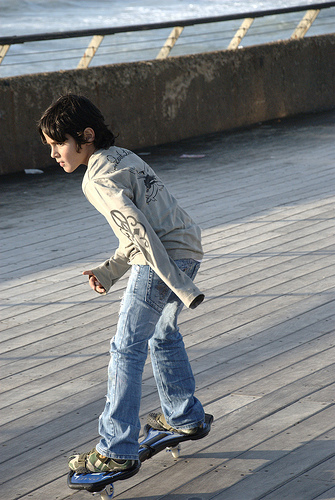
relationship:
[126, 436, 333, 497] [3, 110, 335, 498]
shadow on floor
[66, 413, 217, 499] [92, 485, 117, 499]
skateboard has wheels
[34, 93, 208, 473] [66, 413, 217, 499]
boy on top of skateboard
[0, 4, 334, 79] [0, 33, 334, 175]
surf behind wall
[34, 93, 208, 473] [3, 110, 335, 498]
boy skateboarding on floor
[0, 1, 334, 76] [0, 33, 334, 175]
railing on wall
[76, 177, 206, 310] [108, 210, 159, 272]
sleeve has design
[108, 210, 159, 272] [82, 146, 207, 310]
design on sweater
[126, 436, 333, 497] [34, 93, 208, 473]
shadow behind boy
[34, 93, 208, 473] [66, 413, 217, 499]
boy riding on skateboard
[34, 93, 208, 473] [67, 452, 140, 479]
boy has left foot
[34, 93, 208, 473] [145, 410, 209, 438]
boy has right foot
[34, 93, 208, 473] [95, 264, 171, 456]
boy has left leg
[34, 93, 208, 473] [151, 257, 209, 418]
boy has right leg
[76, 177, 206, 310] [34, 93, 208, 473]
sleeve on boy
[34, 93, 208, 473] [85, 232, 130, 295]
boy has right arm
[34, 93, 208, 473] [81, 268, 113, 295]
boy has right hand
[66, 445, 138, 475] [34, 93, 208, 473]
shoes on boy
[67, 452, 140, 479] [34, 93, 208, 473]
left foot on boy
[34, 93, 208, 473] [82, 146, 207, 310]
boy has sweater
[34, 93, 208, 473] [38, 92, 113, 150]
boy has hair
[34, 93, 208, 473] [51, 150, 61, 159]
boy has nose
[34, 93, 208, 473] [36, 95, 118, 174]
boy has head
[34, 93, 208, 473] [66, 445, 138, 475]
boy has shoes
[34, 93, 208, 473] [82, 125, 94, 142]
boy has left ear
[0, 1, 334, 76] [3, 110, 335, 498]
railing next to floor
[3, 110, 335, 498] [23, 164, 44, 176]
floor has paper